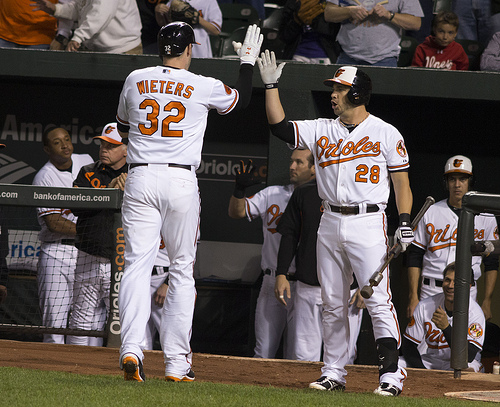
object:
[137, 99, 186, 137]
number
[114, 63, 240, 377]
uniform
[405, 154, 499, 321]
player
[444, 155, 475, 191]
helmet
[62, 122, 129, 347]
man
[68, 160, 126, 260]
jacket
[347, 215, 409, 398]
leg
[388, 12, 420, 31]
man's forearm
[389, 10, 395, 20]
wristwatch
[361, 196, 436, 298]
bat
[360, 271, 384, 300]
weight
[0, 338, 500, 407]
ground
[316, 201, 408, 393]
pant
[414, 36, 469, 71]
sweatshirt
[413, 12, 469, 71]
boy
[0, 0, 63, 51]
spectators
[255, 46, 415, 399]
player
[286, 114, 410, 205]
jersey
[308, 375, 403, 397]
sneaker pair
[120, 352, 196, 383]
sneaker pair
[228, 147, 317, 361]
man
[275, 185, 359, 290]
black shirt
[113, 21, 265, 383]
player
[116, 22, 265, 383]
baseball player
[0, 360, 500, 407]
grass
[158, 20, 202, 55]
helmet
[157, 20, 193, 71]
head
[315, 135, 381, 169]
orioles logo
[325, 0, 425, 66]
shirt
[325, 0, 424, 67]
person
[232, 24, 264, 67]
glove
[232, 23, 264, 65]
hand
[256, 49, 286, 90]
hand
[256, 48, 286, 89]
glove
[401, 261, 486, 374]
player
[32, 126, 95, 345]
player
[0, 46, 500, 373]
dugout